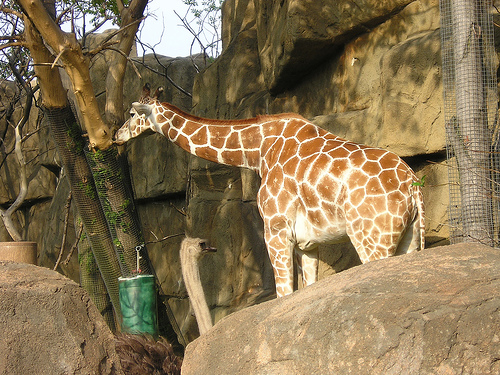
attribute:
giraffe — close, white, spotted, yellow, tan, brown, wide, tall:
[108, 86, 432, 267]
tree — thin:
[13, 0, 204, 325]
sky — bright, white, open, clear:
[3, 1, 227, 72]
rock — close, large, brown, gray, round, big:
[4, 261, 107, 374]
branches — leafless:
[2, 14, 210, 104]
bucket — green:
[108, 264, 159, 340]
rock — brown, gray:
[179, 229, 477, 373]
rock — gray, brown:
[2, 256, 118, 373]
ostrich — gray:
[172, 230, 219, 340]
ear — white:
[129, 98, 156, 119]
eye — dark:
[126, 111, 136, 121]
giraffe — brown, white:
[111, 81, 432, 301]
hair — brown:
[152, 97, 299, 127]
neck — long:
[154, 106, 297, 176]